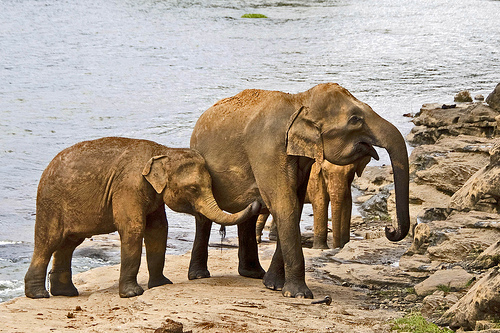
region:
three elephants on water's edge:
[22, 76, 422, 309]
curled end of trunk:
[372, 198, 424, 250]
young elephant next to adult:
[24, 115, 239, 303]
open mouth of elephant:
[348, 137, 392, 162]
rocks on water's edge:
[403, 85, 488, 158]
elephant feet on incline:
[151, 255, 260, 296]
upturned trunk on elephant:
[199, 198, 277, 228]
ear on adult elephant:
[279, 100, 329, 167]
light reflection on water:
[355, 40, 452, 72]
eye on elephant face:
[334, 106, 373, 134]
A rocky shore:
[1, 91, 476, 327]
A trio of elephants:
[15, 70, 385, 300]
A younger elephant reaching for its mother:
[40, 121, 217, 288]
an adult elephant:
[151, 57, 411, 292]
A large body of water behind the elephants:
[0, 5, 471, 240]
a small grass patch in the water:
[230, 5, 275, 20]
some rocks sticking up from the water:
[451, 78, 498, 104]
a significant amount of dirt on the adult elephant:
[206, 60, 356, 110]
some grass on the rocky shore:
[395, 296, 465, 328]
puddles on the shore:
[370, 211, 441, 272]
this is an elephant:
[220, 97, 357, 190]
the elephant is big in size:
[232, 100, 322, 179]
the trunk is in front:
[210, 190, 263, 232]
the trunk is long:
[379, 137, 431, 239]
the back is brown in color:
[64, 143, 131, 203]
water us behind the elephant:
[70, 20, 180, 110]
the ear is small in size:
[139, 152, 174, 194]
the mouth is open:
[359, 140, 379, 160]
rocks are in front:
[429, 164, 493, 274]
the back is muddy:
[222, 88, 261, 120]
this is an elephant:
[41, 135, 185, 275]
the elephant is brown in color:
[218, 110, 272, 148]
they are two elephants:
[53, 101, 401, 331]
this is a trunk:
[371, 130, 413, 247]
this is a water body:
[50, 25, 227, 132]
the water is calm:
[29, 28, 166, 100]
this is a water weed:
[240, 10, 267, 15]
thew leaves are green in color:
[240, 12, 258, 17]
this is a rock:
[447, 147, 497, 299]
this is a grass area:
[386, 309, 408, 327]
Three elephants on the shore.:
[7, 59, 432, 316]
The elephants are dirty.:
[20, 45, 417, 302]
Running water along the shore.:
[16, 2, 495, 303]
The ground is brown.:
[2, 254, 398, 331]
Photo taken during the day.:
[2, 9, 493, 326]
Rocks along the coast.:
[352, 56, 488, 323]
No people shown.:
[1, 7, 496, 327]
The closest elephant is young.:
[4, 115, 271, 302]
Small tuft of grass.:
[379, 304, 464, 329]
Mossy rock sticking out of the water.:
[233, 6, 288, 30]